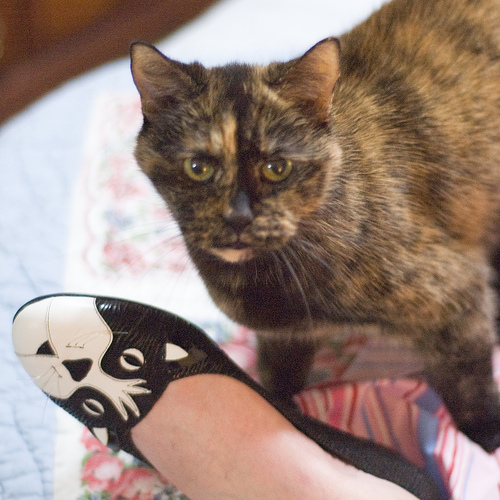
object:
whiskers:
[108, 229, 204, 281]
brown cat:
[128, 0, 500, 456]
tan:
[127, 0, 498, 454]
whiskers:
[272, 207, 375, 353]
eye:
[262, 159, 293, 182]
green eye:
[183, 158, 215, 182]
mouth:
[209, 218, 255, 260]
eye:
[120, 348, 144, 371]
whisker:
[277, 245, 322, 359]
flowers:
[79, 428, 173, 499]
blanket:
[0, 0, 500, 500]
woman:
[11, 290, 449, 500]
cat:
[11, 293, 191, 453]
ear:
[165, 342, 189, 362]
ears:
[128, 36, 342, 122]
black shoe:
[8, 293, 441, 500]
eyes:
[182, 156, 293, 183]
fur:
[237, 100, 330, 200]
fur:
[181, 100, 235, 182]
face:
[134, 78, 327, 246]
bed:
[0, 0, 497, 499]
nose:
[222, 191, 252, 233]